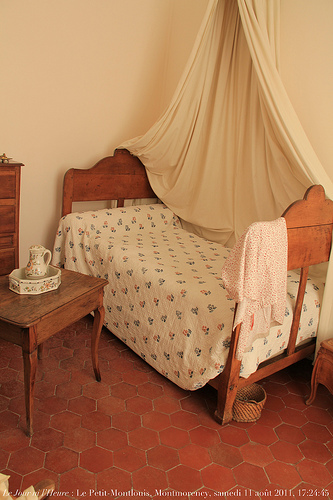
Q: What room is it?
A: It is a bedroom.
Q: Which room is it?
A: It is a bedroom.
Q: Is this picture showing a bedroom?
A: Yes, it is showing a bedroom.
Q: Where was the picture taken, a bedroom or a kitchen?
A: It was taken at a bedroom.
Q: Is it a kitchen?
A: No, it is a bedroom.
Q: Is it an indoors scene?
A: Yes, it is indoors.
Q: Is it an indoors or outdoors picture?
A: It is indoors.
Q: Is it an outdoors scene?
A: No, it is indoors.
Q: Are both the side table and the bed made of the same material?
A: Yes, both the side table and the bed are made of wood.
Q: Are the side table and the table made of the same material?
A: Yes, both the side table and the table are made of wood.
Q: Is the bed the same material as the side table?
A: Yes, both the bed and the side table are made of wood.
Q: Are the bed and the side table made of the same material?
A: Yes, both the bed and the side table are made of wood.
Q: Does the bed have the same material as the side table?
A: Yes, both the bed and the side table are made of wood.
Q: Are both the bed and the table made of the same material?
A: Yes, both the bed and the table are made of wood.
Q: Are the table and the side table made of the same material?
A: Yes, both the table and the side table are made of wood.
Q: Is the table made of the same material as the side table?
A: Yes, both the table and the side table are made of wood.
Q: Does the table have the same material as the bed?
A: Yes, both the table and the bed are made of wood.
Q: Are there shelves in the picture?
A: No, there are no shelves.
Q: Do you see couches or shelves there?
A: No, there are no shelves or couches.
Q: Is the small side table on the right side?
A: Yes, the side table is on the right of the image.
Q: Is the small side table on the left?
A: No, the side table is on the right of the image.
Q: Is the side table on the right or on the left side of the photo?
A: The side table is on the right of the image.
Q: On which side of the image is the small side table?
A: The side table is on the right of the image.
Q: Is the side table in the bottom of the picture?
A: Yes, the side table is in the bottom of the image.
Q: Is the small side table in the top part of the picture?
A: No, the side table is in the bottom of the image.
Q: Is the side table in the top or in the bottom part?
A: The side table is in the bottom of the image.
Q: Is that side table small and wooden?
A: Yes, the side table is small and wooden.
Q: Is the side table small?
A: Yes, the side table is small.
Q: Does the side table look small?
A: Yes, the side table is small.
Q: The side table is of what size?
A: The side table is small.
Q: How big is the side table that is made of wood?
A: The side table is small.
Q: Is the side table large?
A: No, the side table is small.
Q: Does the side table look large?
A: No, the side table is small.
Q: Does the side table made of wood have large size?
A: No, the side table is small.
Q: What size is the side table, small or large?
A: The side table is small.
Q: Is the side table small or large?
A: The side table is small.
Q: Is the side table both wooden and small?
A: Yes, the side table is wooden and small.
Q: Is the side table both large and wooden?
A: No, the side table is wooden but small.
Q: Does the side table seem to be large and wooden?
A: No, the side table is wooden but small.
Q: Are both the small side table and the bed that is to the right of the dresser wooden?
A: Yes, both the side table and the bed are wooden.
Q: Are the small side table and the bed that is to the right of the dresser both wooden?
A: Yes, both the side table and the bed are wooden.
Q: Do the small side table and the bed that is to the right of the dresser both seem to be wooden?
A: Yes, both the side table and the bed are wooden.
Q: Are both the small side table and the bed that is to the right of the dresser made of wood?
A: Yes, both the side table and the bed are made of wood.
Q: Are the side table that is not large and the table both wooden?
A: Yes, both the side table and the table are wooden.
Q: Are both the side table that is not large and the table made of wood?
A: Yes, both the side table and the table are made of wood.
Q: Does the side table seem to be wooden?
A: Yes, the side table is wooden.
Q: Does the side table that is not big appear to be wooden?
A: Yes, the side table is wooden.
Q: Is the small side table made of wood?
A: Yes, the side table is made of wood.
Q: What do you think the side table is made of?
A: The side table is made of wood.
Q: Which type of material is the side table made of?
A: The side table is made of wood.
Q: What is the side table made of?
A: The side table is made of wood.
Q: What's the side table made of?
A: The side table is made of wood.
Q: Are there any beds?
A: Yes, there is a bed.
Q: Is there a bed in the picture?
A: Yes, there is a bed.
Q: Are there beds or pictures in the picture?
A: Yes, there is a bed.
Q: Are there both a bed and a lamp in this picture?
A: No, there is a bed but no lamps.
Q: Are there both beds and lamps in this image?
A: No, there is a bed but no lamps.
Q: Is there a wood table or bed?
A: Yes, there is a wood bed.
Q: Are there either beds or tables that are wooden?
A: Yes, the bed is wooden.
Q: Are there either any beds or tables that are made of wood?
A: Yes, the bed is made of wood.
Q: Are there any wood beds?
A: Yes, there is a wood bed.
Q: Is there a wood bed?
A: Yes, there is a wood bed.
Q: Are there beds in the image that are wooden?
A: Yes, there is a bed that is wooden.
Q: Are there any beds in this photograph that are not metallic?
A: Yes, there is a wooden bed.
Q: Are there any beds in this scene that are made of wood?
A: Yes, there is a bed that is made of wood.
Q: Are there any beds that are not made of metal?
A: Yes, there is a bed that is made of wood.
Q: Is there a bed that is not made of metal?
A: Yes, there is a bed that is made of wood.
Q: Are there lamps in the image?
A: No, there are no lamps.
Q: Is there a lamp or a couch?
A: No, there are no lamps or couches.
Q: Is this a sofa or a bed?
A: This is a bed.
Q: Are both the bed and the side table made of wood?
A: Yes, both the bed and the side table are made of wood.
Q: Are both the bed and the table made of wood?
A: Yes, both the bed and the table are made of wood.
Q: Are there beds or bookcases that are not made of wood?
A: No, there is a bed but it is made of wood.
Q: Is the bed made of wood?
A: Yes, the bed is made of wood.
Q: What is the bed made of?
A: The bed is made of wood.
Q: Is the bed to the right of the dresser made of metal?
A: No, the bed is made of wood.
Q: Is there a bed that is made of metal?
A: No, there is a bed but it is made of wood.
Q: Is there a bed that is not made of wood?
A: No, there is a bed but it is made of wood.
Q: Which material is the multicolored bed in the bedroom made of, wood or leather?
A: The bed is made of wood.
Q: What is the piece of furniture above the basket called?
A: The piece of furniture is a bed.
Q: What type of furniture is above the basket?
A: The piece of furniture is a bed.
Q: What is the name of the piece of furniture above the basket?
A: The piece of furniture is a bed.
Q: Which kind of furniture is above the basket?
A: The piece of furniture is a bed.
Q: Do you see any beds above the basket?
A: Yes, there is a bed above the basket.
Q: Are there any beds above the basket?
A: Yes, there is a bed above the basket.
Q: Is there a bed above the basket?
A: Yes, there is a bed above the basket.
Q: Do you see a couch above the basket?
A: No, there is a bed above the basket.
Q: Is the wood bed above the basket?
A: Yes, the bed is above the basket.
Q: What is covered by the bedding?
A: The bed is covered by the bedding.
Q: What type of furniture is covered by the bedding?
A: The piece of furniture is a bed.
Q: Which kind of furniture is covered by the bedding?
A: The piece of furniture is a bed.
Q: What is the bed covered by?
A: The bed is covered by the bedding.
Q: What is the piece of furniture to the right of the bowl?
A: The piece of furniture is a bed.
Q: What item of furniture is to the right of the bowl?
A: The piece of furniture is a bed.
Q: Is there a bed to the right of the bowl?
A: Yes, there is a bed to the right of the bowl.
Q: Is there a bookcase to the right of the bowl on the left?
A: No, there is a bed to the right of the bowl.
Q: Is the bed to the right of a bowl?
A: Yes, the bed is to the right of a bowl.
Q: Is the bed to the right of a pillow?
A: No, the bed is to the right of a bowl.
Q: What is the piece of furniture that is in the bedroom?
A: The piece of furniture is a bed.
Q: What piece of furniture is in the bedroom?
A: The piece of furniture is a bed.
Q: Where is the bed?
A: The bed is in the bedroom.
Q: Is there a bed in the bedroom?
A: Yes, there is a bed in the bedroom.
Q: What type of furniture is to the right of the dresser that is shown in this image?
A: The piece of furniture is a bed.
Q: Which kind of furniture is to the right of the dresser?
A: The piece of furniture is a bed.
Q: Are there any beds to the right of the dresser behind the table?
A: Yes, there is a bed to the right of the dresser.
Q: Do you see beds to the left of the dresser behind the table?
A: No, the bed is to the right of the dresser.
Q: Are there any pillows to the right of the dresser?
A: No, there is a bed to the right of the dresser.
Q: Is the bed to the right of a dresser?
A: Yes, the bed is to the right of a dresser.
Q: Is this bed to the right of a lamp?
A: No, the bed is to the right of a dresser.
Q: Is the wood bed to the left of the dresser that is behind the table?
A: No, the bed is to the right of the dresser.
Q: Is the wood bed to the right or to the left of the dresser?
A: The bed is to the right of the dresser.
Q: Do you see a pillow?
A: No, there are no pillows.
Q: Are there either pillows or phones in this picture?
A: No, there are no pillows or phones.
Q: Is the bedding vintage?
A: Yes, the bedding is vintage.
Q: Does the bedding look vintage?
A: Yes, the bedding is vintage.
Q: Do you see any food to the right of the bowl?
A: No, there is bedding to the right of the bowl.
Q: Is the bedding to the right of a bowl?
A: Yes, the bedding is to the right of a bowl.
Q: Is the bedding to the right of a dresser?
A: Yes, the bedding is to the right of a dresser.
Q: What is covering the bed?
A: The bedding is covering the bed.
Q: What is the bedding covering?
A: The bedding is covering the bed.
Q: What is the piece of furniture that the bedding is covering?
A: The piece of furniture is a bed.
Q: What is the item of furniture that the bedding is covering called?
A: The piece of furniture is a bed.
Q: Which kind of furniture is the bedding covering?
A: The bedding is covering the bed.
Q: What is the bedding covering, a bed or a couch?
A: The bedding is covering a bed.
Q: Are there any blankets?
A: Yes, there is a blanket.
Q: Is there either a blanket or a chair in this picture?
A: Yes, there is a blanket.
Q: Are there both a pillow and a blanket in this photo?
A: No, there is a blanket but no pillows.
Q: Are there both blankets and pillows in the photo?
A: No, there is a blanket but no pillows.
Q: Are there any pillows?
A: No, there are no pillows.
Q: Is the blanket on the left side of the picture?
A: No, the blanket is on the right of the image.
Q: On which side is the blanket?
A: The blanket is on the right of the image.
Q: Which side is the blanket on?
A: The blanket is on the right of the image.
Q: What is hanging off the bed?
A: The blanket is hanging off the bed.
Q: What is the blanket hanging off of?
A: The blanket is hanging off the bed.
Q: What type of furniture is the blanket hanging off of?
A: The blanket is hanging off the bed.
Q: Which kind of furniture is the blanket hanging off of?
A: The blanket is hanging off the bed.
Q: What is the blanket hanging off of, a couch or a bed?
A: The blanket is hanging off a bed.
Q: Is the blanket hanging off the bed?
A: Yes, the blanket is hanging off the bed.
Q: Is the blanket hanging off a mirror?
A: No, the blanket is hanging off the bed.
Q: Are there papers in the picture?
A: No, there are no papers.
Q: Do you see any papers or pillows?
A: No, there are no papers or pillows.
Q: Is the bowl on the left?
A: Yes, the bowl is on the left of the image.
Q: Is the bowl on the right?
A: No, the bowl is on the left of the image.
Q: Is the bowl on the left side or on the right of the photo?
A: The bowl is on the left of the image.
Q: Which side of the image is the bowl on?
A: The bowl is on the left of the image.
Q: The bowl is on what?
A: The bowl is on the table.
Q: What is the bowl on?
A: The bowl is on the table.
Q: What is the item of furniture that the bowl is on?
A: The piece of furniture is a table.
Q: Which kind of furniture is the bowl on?
A: The bowl is on the table.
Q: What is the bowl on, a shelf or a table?
A: The bowl is on a table.